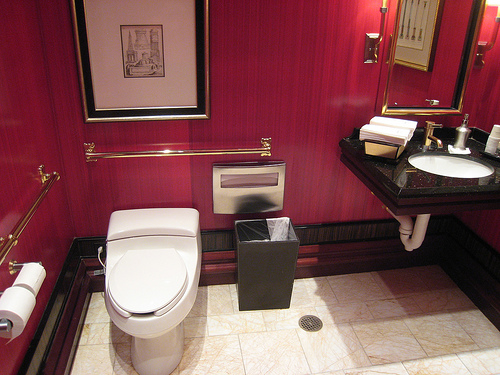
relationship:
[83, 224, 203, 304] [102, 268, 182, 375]
lid on a toilet seat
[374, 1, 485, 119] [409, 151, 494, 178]
mirror above sink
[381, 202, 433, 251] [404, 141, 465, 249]
drainage pipe under sink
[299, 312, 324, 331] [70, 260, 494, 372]
drainer on floor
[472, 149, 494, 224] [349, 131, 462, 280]
soap dispenser on sink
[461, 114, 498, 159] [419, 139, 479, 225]
cups by sink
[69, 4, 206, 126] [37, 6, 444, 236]
picture on wall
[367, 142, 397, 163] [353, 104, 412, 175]
basket of paper towels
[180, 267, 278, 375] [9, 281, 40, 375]
toilet paper rolls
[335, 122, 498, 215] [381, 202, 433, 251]
marble sink has drainage pipe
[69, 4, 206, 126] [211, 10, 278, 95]
picture on wall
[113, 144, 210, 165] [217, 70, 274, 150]
racks on wall